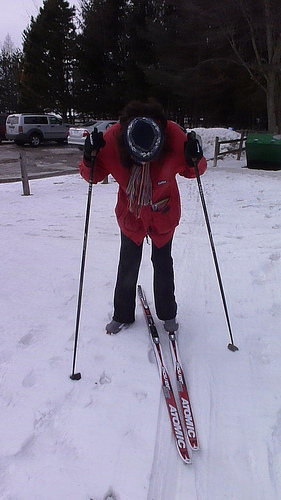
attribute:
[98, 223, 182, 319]
pants — long, dark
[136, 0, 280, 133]
tree — bare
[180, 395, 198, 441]
word — white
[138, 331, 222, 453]
skis — white, Red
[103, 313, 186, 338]
shoes — Grey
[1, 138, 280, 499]
ground — covered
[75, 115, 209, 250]
jacket — red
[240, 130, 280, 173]
container — trash container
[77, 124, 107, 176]
hand — gloved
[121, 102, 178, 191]
hair — long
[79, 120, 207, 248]
parka — red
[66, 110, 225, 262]
coat — red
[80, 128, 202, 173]
gloves — Black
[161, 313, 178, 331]
boot — gray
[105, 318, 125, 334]
boot — gray